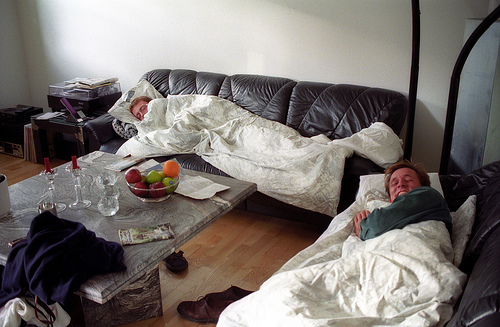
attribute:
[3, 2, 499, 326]
room — living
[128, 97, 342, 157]
man — laying, sleeping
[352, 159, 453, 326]
man — laying, sleeping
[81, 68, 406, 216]
couch — leathery, black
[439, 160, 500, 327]
couch — leathery, black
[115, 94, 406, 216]
blanket — white, wrinkled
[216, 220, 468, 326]
blanket — white, wrinkled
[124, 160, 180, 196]
fruit — fresh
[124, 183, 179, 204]
bowl — glassy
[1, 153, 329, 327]
floor — woody, brown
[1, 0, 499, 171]
walls — white, behind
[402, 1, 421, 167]
railings — black, large, behind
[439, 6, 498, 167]
railings — black, large, behind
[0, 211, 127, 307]
clothing — blue, sitting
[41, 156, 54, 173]
candle — red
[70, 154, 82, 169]
candle — red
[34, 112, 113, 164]
table — small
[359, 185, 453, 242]
shirt — green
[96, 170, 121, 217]
glassware — glassy